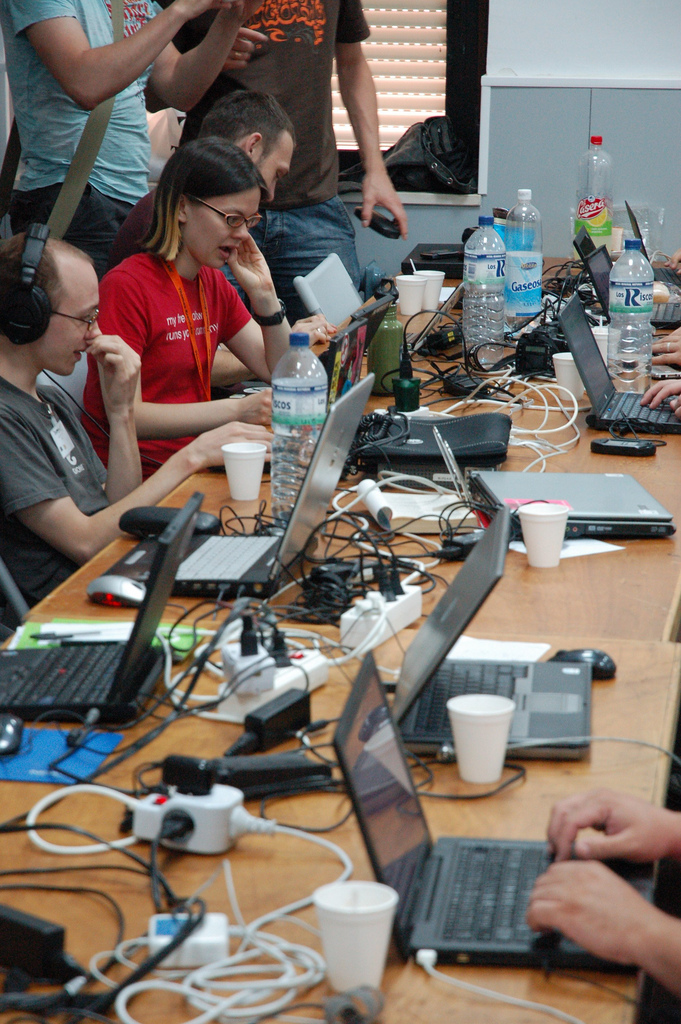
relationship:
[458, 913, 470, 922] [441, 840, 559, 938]
button on keyboard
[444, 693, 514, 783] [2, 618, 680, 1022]
styrofoam on table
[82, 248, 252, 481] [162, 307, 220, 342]
tee shirt with print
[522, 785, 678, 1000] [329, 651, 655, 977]
man using computer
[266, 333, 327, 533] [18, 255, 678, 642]
water bottle on table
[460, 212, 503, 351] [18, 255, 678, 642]
water bottle on table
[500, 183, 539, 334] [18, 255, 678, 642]
water bottle on table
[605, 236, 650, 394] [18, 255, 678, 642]
water bottle on table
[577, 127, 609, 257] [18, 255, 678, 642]
water bottle on table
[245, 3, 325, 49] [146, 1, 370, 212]
design on shirt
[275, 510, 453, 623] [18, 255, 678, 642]
cords sitting on table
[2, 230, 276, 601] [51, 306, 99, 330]
person wears glasses